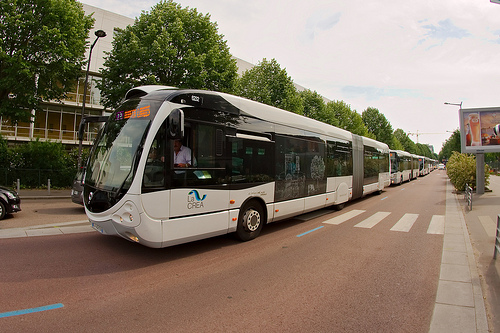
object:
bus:
[389, 149, 419, 186]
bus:
[418, 152, 438, 174]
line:
[294, 219, 326, 239]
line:
[377, 192, 389, 201]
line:
[398, 184, 406, 192]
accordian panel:
[349, 130, 364, 203]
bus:
[410, 154, 434, 179]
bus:
[77, 80, 393, 253]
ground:
[304, 158, 353, 225]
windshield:
[82, 96, 164, 212]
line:
[2, 296, 83, 316]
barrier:
[449, 176, 479, 200]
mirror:
[168, 111, 185, 131]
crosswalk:
[321, 198, 447, 236]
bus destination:
[111, 105, 153, 123]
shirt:
[168, 145, 198, 171]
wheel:
[239, 205, 265, 240]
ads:
[272, 132, 329, 203]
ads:
[328, 141, 353, 175]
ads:
[364, 145, 381, 187]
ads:
[379, 153, 390, 173]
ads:
[402, 160, 410, 170]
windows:
[188, 129, 277, 184]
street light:
[80, 27, 106, 124]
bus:
[67, 70, 442, 277]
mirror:
[167, 142, 220, 183]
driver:
[160, 130, 197, 174]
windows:
[281, 139, 352, 178]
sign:
[118, 100, 151, 120]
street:
[3, 165, 498, 315]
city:
[12, 151, 498, 325]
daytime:
[6, 5, 498, 331]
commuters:
[193, 133, 349, 168]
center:
[346, 130, 367, 197]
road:
[12, 24, 472, 331]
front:
[85, 81, 158, 238]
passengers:
[235, 118, 430, 178]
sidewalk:
[420, 194, 473, 326]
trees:
[5, 4, 441, 199]